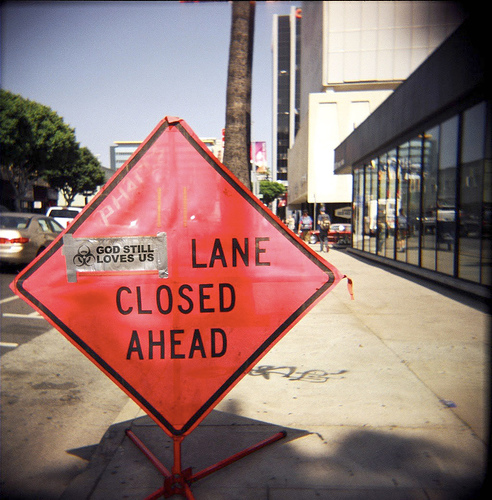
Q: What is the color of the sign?
A: Orange.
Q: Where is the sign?
A: On street.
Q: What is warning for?
A: Road.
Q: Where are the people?
A: Sidewalk.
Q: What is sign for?
A: Traffic.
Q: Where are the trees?
A: Sidewalk.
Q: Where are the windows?
A: On building.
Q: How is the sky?
A: Clear.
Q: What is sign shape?
A: Triangle.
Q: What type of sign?
A: Construction.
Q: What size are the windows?
A: Large.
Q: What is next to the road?
A: Tall tree.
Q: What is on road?
A: Construction sign.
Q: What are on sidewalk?
A: Shadows.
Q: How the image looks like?
A: Good.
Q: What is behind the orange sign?
A: Tree trunk.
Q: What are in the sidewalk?
A: Walk.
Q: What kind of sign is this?
A: Construction.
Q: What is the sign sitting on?
A: Sidewalk.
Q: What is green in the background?
A: Trees.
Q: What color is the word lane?
A: Black.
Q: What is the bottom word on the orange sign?
A: Ahead.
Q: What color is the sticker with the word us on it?
A: Silver.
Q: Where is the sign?
A: On the sidewalk.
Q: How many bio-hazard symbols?
A: 1.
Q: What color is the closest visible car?
A: Gold.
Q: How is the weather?
A: Clear.